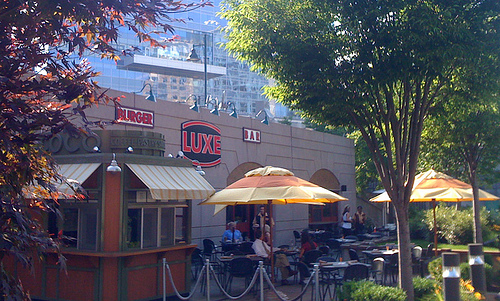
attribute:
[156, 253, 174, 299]
bar — silver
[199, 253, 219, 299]
bar — silver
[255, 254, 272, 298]
bar — silver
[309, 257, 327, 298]
bar — silver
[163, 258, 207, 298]
rope — grey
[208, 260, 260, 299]
rope — grey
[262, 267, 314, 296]
rope — grey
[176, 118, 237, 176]
sign — red, black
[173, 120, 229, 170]
sign — black, red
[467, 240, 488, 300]
barrier — small, white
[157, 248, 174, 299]
bars — silver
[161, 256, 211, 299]
ropes — grey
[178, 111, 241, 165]
text — red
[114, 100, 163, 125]
text — red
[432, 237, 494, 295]
poles — short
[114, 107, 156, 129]
text — red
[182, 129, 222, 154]
text — red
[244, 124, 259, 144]
text — red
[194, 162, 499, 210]
umbrellas — yellow, pink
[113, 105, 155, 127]
sign — white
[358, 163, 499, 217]
umbrella — yellow, orange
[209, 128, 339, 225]
umbrella — open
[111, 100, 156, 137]
sign — red, white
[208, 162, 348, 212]
umbrella — orange, yellow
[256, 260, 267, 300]
bars — silver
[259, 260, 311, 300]
ropes — grey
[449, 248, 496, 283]
barrier — white, small, brick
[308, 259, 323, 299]
pole — white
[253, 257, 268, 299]
pole — white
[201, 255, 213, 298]
pole — white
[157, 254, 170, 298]
pole — white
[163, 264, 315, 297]
chain — white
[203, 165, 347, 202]
umbrella — open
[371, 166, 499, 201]
umbrella — open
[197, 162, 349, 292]
umbrella — orange, yellow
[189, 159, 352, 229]
umbrella — yellow, orange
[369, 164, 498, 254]
umbrella — orange, yellow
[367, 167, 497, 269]
umbrella — yellow, orange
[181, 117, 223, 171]
sign — black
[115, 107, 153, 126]
lettering — red